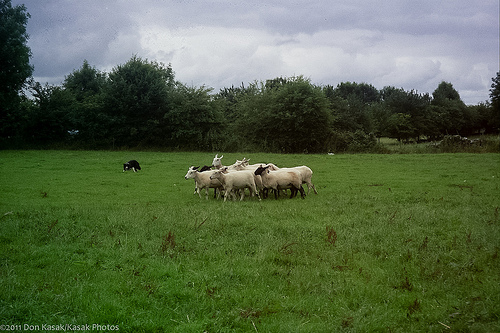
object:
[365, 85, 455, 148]
trees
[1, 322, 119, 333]
name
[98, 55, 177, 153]
tree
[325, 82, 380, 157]
tree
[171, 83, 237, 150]
tree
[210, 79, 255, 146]
tree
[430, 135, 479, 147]
cut wood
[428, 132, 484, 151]
stack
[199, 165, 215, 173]
goats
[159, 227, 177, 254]
brown bushes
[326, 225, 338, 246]
brown bushes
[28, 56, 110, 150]
trees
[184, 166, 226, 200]
goat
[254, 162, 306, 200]
goat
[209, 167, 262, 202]
goat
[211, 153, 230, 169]
goat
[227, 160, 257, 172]
goat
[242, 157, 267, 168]
goat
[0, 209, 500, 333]
field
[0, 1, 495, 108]
sky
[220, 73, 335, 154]
tree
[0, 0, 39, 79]
leaves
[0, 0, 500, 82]
cloud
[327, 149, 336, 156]
white stack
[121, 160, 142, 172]
animal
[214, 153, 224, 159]
horns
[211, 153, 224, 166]
animal's head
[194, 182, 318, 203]
legs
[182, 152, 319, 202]
flock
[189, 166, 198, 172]
head horns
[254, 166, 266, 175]
face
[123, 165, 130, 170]
feet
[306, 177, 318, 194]
leg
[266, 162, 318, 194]
goat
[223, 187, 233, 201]
leg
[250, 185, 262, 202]
leg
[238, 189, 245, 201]
leg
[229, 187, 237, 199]
leg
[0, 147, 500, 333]
grass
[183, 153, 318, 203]
pack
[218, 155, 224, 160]
ears